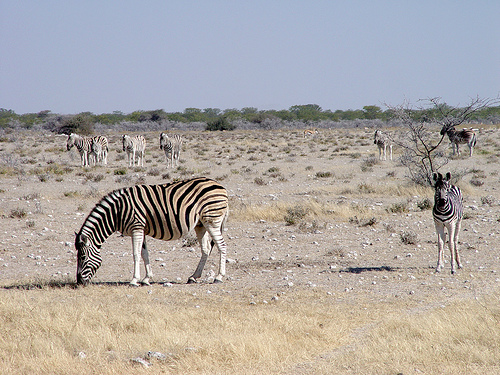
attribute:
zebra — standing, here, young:
[419, 169, 474, 276]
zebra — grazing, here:
[60, 169, 225, 310]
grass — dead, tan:
[253, 203, 343, 219]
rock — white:
[248, 253, 261, 264]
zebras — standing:
[69, 131, 115, 159]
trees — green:
[115, 103, 327, 137]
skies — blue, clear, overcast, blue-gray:
[37, 20, 483, 91]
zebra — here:
[433, 118, 482, 156]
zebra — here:
[158, 125, 186, 157]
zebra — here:
[119, 127, 148, 165]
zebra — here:
[66, 124, 88, 166]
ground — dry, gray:
[243, 253, 428, 324]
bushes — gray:
[82, 118, 209, 130]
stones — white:
[230, 255, 279, 263]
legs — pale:
[428, 218, 464, 266]